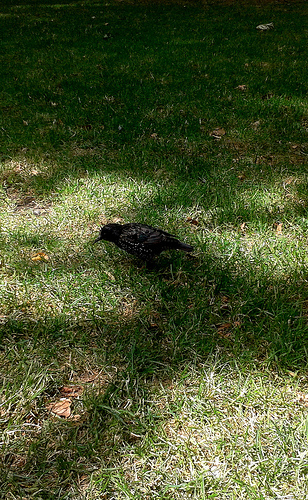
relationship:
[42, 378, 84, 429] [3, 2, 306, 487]
leaf on grass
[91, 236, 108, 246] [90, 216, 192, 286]
beak of bird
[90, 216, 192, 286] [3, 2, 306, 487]
bird in grass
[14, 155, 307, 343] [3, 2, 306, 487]
sunlight on grass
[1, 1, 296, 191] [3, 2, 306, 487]
shadow on grass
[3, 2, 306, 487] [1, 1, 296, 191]
grass has shadow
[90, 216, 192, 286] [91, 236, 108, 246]
bird has beak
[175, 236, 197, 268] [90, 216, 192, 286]
tail of bird